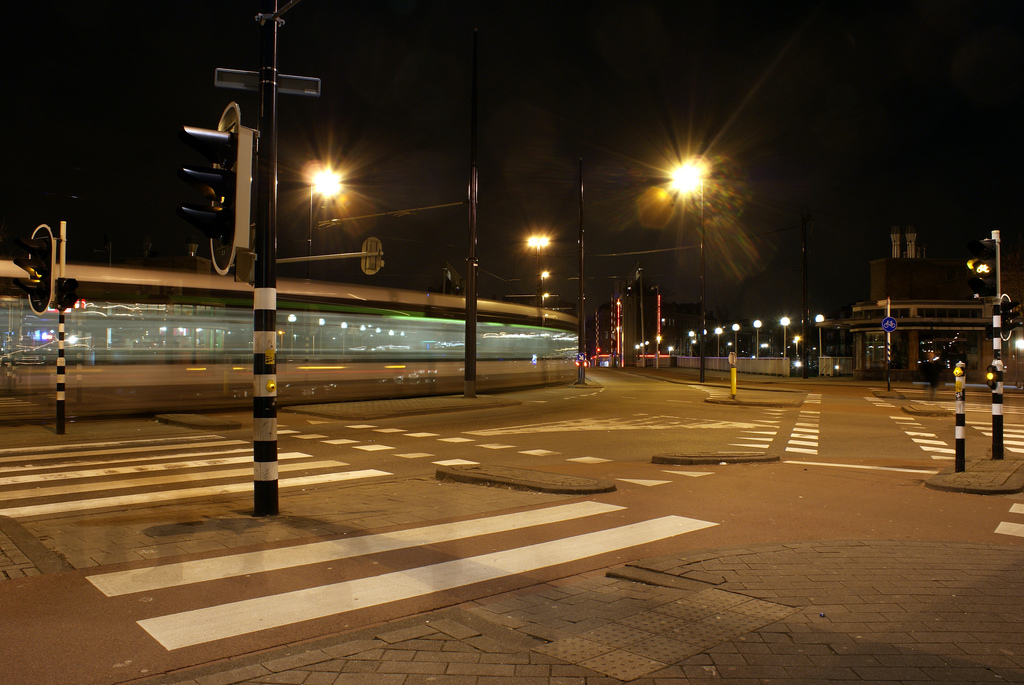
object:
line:
[134, 516, 718, 652]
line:
[87, 500, 631, 598]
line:
[77, 468, 104, 477]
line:
[161, 435, 226, 439]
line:
[430, 458, 480, 466]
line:
[781, 459, 939, 474]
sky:
[767, 37, 954, 165]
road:
[0, 367, 1024, 684]